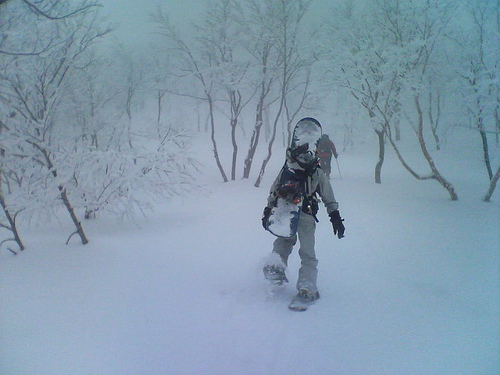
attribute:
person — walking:
[255, 105, 353, 310]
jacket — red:
[317, 141, 340, 166]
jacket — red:
[315, 135, 342, 158]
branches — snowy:
[47, 64, 179, 219]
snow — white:
[112, 246, 261, 312]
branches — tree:
[62, 126, 171, 196]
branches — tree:
[354, 29, 455, 200]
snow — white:
[199, 206, 245, 265]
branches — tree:
[196, 30, 299, 112]